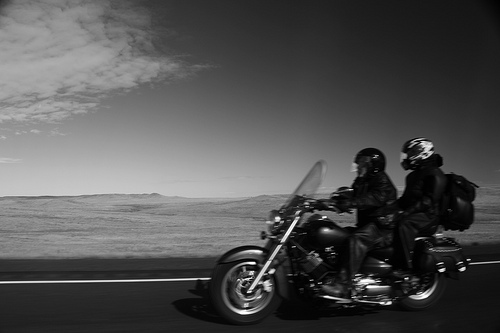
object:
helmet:
[352, 147, 387, 178]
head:
[354, 147, 388, 178]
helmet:
[399, 137, 434, 170]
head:
[401, 137, 433, 169]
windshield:
[276, 159, 324, 217]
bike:
[211, 160, 469, 325]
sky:
[6, 14, 499, 194]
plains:
[1, 183, 500, 260]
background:
[5, 5, 500, 257]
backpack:
[437, 172, 479, 231]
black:
[410, 212, 428, 230]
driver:
[319, 148, 399, 299]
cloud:
[4, 8, 201, 147]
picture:
[4, 3, 499, 321]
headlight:
[267, 210, 277, 233]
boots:
[322, 281, 350, 298]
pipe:
[315, 295, 394, 307]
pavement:
[3, 248, 499, 327]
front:
[209, 160, 342, 323]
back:
[393, 135, 481, 301]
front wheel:
[209, 257, 283, 325]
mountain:
[6, 191, 499, 256]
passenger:
[373, 135, 448, 278]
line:
[0, 256, 500, 285]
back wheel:
[400, 273, 448, 309]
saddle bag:
[413, 237, 466, 273]